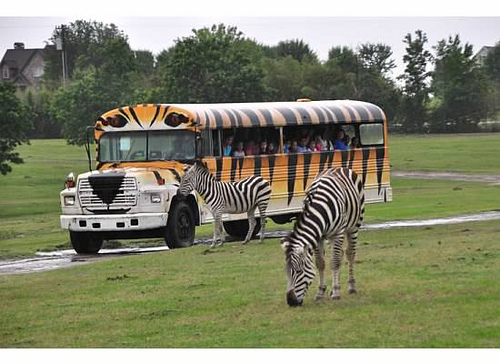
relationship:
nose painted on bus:
[80, 165, 133, 209] [37, 101, 439, 244]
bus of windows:
[57, 97, 397, 253] [202, 120, 376, 158]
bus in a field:
[56, 92, 396, 252] [22, 242, 482, 351]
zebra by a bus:
[175, 153, 274, 251] [56, 92, 396, 252]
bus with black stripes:
[57, 97, 397, 253] [197, 103, 381, 193]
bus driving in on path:
[56, 92, 396, 252] [1, 205, 481, 283]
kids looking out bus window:
[50, 80, 401, 303] [192, 116, 385, 154]